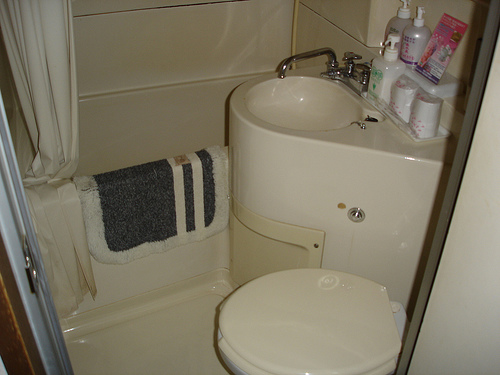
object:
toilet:
[217, 267, 403, 375]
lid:
[217, 268, 401, 375]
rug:
[73, 145, 230, 266]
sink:
[229, 65, 443, 302]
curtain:
[0, 0, 98, 318]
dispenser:
[367, 34, 406, 108]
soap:
[369, 74, 398, 99]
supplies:
[368, 1, 469, 139]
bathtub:
[16, 69, 266, 210]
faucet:
[278, 47, 370, 95]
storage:
[229, 196, 325, 290]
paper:
[414, 13, 468, 85]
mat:
[72, 145, 230, 265]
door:
[0, 95, 74, 375]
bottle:
[367, 33, 406, 109]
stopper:
[351, 115, 379, 130]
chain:
[350, 120, 362, 126]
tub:
[245, 76, 362, 131]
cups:
[389, 77, 442, 139]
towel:
[27, 189, 97, 320]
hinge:
[20, 235, 39, 294]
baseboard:
[60, 274, 230, 374]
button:
[347, 208, 365, 223]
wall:
[67, 1, 291, 96]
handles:
[342, 48, 373, 90]